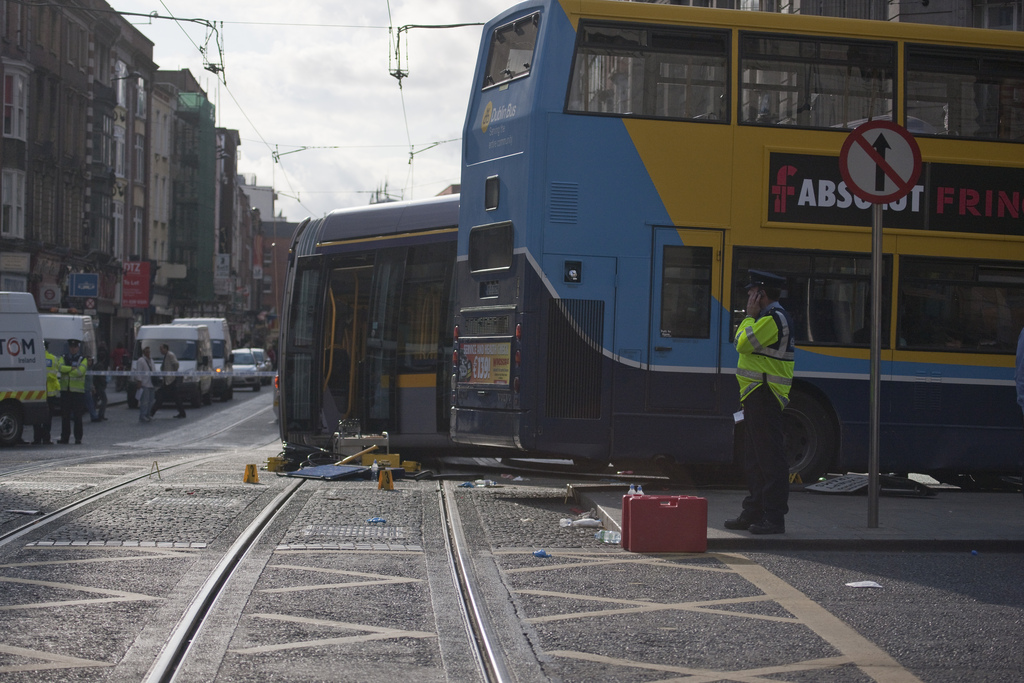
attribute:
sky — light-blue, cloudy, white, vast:
[131, 8, 568, 243]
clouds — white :
[253, 67, 353, 176]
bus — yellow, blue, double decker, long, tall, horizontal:
[471, 77, 1022, 482]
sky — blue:
[103, 6, 514, 219]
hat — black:
[743, 257, 797, 297]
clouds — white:
[249, 101, 361, 197]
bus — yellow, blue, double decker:
[455, 17, 1007, 521]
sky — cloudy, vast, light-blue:
[201, 14, 313, 104]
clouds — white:
[222, 56, 328, 120]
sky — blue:
[197, 14, 416, 201]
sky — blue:
[0, 3, 1024, 243]